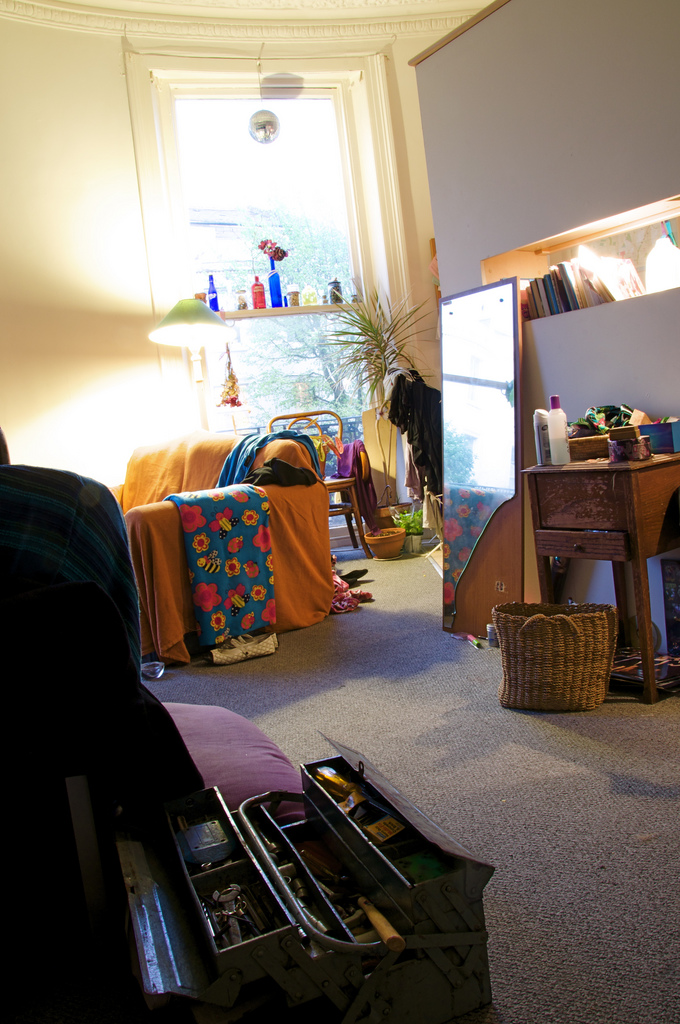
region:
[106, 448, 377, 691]
The blue blanket is on the yellow blanket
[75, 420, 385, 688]
The yellow blanket is draped over the couch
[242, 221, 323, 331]
Flowers in the blue bottle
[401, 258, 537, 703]
The broken mirror is leaning against the wall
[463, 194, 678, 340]
The books are on the shelf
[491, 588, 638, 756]
The wicker bag is on the floor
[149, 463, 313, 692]
The blue blanket has yellow bees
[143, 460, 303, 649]
The blue blanket has pink flowers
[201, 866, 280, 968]
The tool box has a wrench inside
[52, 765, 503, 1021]
toolbox open on ground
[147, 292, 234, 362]
green lamp turned on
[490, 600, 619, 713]
basket sitting on floor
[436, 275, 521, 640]
broken mirror leaning against wlal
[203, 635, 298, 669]
black and white flats next to couch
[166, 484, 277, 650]
blue blanket with bumble bees and flowers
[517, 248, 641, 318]
books sitting on book shelf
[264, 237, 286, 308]
flowers in a wine bottle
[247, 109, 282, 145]
disco ball hanging in window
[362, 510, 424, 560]
plants sitting on floor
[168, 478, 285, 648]
blanket with bees and flowers on it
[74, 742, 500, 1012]
metal multi layered tool box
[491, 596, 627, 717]
soft sided wicker basket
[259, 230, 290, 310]
blue glass bottles being used as a vase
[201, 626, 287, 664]
white shoes with black toes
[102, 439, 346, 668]
couch covered in orange cloth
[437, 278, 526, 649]
broken mirror sitting on the floor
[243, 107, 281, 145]
mini disco ball hanging in a window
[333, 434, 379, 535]
purple blanket draped over a chair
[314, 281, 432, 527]
potted tree sitting by a window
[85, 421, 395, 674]
Chair with yellow blanket on it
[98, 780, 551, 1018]
Old metal toolbox filled with tools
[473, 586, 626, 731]
Small wicker basket in room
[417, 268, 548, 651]
Full length mirror in the room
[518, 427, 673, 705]
Small end table in the room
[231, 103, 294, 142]
disco ball hanging from ceiling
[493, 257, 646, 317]
Row of books in the room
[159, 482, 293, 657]
Blanket with flowers and bees on it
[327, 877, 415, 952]
Hammer inside old tool box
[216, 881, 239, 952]
A tool in a toolbox.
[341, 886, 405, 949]
A tool in a toolbox.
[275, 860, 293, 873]
A tool in a toolbox.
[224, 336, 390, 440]
glass is clean and clear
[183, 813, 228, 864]
tool is in a bag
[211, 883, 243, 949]
tool is in a bag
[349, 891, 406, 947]
tool is in a bag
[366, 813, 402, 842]
tool is in a bag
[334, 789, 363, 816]
tool is in a bag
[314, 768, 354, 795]
tool is in a bag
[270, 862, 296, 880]
tool is in a bag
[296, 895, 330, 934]
tool is in a bag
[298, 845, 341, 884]
tool is in a bag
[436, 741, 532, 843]
carpet is light grey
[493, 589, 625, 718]
brown and wicker basket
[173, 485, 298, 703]
child's blanket on chair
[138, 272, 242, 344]
lamp is behind chair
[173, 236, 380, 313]
bottles are on ledge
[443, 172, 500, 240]
white wall behind chair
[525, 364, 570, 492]
bottles sitting on table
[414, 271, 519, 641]
mirror next to chair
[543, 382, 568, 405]
purple lid on bottle